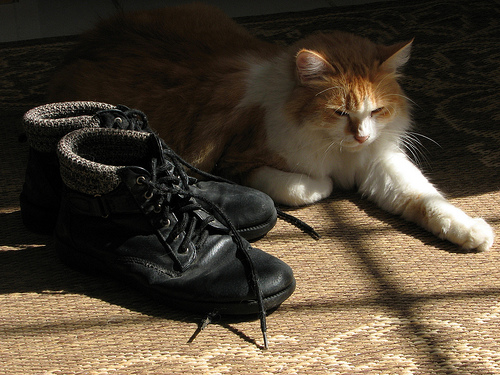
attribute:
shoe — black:
[57, 125, 297, 321]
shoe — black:
[21, 97, 280, 242]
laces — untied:
[142, 176, 269, 349]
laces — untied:
[114, 103, 321, 239]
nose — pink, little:
[335, 127, 383, 142]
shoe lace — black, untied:
[156, 187, 270, 352]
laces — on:
[153, 151, 327, 355]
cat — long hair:
[180, 34, 495, 251]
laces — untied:
[132, 168, 227, 255]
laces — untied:
[108, 106, 193, 173]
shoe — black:
[18, 97, 296, 322]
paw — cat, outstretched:
[434, 203, 496, 255]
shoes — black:
[11, 104, 304, 322]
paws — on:
[308, 179, 495, 261]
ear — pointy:
[284, 41, 349, 81]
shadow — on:
[0, 5, 499, 330]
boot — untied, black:
[19, 88, 301, 318]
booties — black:
[22, 98, 319, 350]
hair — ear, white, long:
[309, 58, 321, 71]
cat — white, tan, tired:
[50, 7, 499, 257]